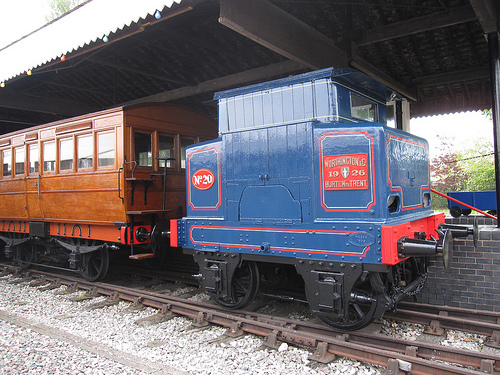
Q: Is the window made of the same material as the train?
A: No, the window is made of glass and the train is made of metal.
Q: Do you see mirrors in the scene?
A: No, there are no mirrors.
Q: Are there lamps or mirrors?
A: No, there are no mirrors or lamps.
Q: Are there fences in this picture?
A: No, there are no fences.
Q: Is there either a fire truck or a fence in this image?
A: No, there are no fences or fire trucks.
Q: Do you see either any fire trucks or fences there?
A: No, there are no fences or fire trucks.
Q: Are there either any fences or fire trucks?
A: No, there are no fences or fire trucks.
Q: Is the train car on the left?
A: Yes, the train car is on the left of the image.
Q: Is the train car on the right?
A: No, the train car is on the left of the image.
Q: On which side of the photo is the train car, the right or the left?
A: The train car is on the left of the image.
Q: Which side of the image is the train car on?
A: The train car is on the left of the image.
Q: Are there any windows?
A: Yes, there is a window.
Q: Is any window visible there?
A: Yes, there is a window.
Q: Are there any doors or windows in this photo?
A: Yes, there is a window.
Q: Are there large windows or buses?
A: Yes, there is a large window.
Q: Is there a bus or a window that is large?
A: Yes, the window is large.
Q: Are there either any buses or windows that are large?
A: Yes, the window is large.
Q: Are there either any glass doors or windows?
A: Yes, there is a glass window.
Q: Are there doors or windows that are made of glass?
A: Yes, the window is made of glass.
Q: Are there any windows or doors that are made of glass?
A: Yes, the window is made of glass.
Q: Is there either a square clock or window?
A: Yes, there is a square window.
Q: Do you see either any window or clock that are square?
A: Yes, the window is square.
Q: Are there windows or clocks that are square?
A: Yes, the window is square.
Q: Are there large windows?
A: Yes, there is a large window.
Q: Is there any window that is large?
A: Yes, there is a window that is large.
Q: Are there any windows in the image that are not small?
A: Yes, there is a large window.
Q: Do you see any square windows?
A: Yes, there is a square window.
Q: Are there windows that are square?
A: Yes, there is a window that is square.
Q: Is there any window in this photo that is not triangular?
A: Yes, there is a square window.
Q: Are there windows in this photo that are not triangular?
A: Yes, there is a square window.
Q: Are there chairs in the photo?
A: No, there are no chairs.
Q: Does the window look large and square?
A: Yes, the window is large and square.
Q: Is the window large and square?
A: Yes, the window is large and square.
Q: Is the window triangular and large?
A: No, the window is large but square.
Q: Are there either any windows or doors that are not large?
A: No, there is a window but it is large.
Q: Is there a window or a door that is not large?
A: No, there is a window but it is large.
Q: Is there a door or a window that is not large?
A: No, there is a window but it is large.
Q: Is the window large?
A: Yes, the window is large.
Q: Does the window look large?
A: Yes, the window is large.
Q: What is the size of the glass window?
A: The window is large.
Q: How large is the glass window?
A: The window is large.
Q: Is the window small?
A: No, the window is large.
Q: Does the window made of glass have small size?
A: No, the window is large.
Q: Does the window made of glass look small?
A: No, the window is large.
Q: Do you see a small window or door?
A: No, there is a window but it is large.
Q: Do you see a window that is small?
A: No, there is a window but it is large.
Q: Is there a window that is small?
A: No, there is a window but it is large.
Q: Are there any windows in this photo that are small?
A: No, there is a window but it is large.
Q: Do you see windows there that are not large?
A: No, there is a window but it is large.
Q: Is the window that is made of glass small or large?
A: The window is large.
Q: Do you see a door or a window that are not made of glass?
A: No, there is a window but it is made of glass.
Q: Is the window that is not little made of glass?
A: Yes, the window is made of glass.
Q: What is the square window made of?
A: The window is made of glass.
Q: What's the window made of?
A: The window is made of glass.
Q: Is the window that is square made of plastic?
A: No, the window is made of glass.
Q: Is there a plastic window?
A: No, there is a window but it is made of glass.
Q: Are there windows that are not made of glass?
A: No, there is a window but it is made of glass.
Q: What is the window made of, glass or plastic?
A: The window is made of glass.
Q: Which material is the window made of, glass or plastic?
A: The window is made of glass.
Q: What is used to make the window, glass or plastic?
A: The window is made of glass.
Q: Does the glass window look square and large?
A: Yes, the window is square and large.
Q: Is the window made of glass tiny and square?
A: No, the window is square but large.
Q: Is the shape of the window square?
A: Yes, the window is square.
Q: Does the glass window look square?
A: Yes, the window is square.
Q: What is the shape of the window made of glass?
A: The window is square.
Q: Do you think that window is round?
A: No, the window is square.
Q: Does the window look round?
A: No, the window is square.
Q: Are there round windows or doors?
A: No, there is a window but it is square.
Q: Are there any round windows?
A: No, there is a window but it is square.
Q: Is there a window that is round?
A: No, there is a window but it is square.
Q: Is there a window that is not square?
A: No, there is a window but it is square.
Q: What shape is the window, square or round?
A: The window is square.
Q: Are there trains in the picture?
A: Yes, there is a train.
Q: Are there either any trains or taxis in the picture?
A: Yes, there is a train.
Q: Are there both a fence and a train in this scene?
A: No, there is a train but no fences.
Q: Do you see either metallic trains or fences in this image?
A: Yes, there is a metal train.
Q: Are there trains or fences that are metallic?
A: Yes, the train is metallic.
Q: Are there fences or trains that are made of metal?
A: Yes, the train is made of metal.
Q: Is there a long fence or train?
A: Yes, there is a long train.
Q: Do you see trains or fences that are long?
A: Yes, the train is long.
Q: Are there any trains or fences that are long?
A: Yes, the train is long.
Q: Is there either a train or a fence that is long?
A: Yes, the train is long.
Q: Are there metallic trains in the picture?
A: Yes, there is a metal train.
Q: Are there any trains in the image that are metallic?
A: Yes, there is a train that is metallic.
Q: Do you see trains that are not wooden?
A: Yes, there is a metallic train.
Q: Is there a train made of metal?
A: Yes, there is a train that is made of metal.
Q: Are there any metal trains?
A: Yes, there is a train that is made of metal.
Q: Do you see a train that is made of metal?
A: Yes, there is a train that is made of metal.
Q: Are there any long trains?
A: Yes, there is a long train.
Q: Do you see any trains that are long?
A: Yes, there is a long train.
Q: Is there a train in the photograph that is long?
A: Yes, there is a train that is long.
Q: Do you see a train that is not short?
A: Yes, there is a long train.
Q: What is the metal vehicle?
A: The vehicle is a train.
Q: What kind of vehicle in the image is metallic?
A: The vehicle is a train.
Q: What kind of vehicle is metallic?
A: The vehicle is a train.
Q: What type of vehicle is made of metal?
A: The vehicle is a train.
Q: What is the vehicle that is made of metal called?
A: The vehicle is a train.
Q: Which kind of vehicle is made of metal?
A: The vehicle is a train.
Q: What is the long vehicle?
A: The vehicle is a train.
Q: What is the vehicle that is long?
A: The vehicle is a train.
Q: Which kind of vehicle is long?
A: The vehicle is a train.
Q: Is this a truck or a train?
A: This is a train.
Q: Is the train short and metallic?
A: No, the train is metallic but long.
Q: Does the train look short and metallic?
A: No, the train is metallic but long.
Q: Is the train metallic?
A: Yes, the train is metallic.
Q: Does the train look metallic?
A: Yes, the train is metallic.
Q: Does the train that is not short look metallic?
A: Yes, the train is metallic.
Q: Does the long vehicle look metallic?
A: Yes, the train is metallic.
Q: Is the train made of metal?
A: Yes, the train is made of metal.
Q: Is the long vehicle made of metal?
A: Yes, the train is made of metal.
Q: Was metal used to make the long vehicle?
A: Yes, the train is made of metal.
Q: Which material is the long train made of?
A: The train is made of metal.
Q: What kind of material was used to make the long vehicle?
A: The train is made of metal.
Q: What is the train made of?
A: The train is made of metal.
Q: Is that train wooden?
A: No, the train is metallic.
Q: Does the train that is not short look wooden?
A: No, the train is metallic.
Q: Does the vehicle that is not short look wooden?
A: No, the train is metallic.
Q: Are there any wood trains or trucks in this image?
A: No, there is a train but it is metallic.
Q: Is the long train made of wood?
A: No, the train is made of metal.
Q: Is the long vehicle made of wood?
A: No, the train is made of metal.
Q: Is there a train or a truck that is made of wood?
A: No, there is a train but it is made of metal.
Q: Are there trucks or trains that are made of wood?
A: No, there is a train but it is made of metal.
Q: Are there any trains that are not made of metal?
A: No, there is a train but it is made of metal.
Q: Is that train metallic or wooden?
A: The train is metallic.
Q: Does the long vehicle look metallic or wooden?
A: The train is metallic.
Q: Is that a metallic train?
A: Yes, that is a metallic train.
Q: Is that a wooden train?
A: No, that is a metallic train.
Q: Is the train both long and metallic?
A: Yes, the train is long and metallic.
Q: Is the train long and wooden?
A: No, the train is long but metallic.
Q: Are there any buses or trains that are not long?
A: No, there is a train but it is long.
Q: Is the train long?
A: Yes, the train is long.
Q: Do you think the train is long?
A: Yes, the train is long.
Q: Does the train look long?
A: Yes, the train is long.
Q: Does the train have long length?
A: Yes, the train is long.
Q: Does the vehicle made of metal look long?
A: Yes, the train is long.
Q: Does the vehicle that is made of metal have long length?
A: Yes, the train is long.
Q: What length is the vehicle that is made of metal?
A: The train is long.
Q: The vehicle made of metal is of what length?
A: The train is long.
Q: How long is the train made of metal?
A: The train is long.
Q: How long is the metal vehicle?
A: The train is long.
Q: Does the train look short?
A: No, the train is long.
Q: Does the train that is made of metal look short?
A: No, the train is long.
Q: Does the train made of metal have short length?
A: No, the train is long.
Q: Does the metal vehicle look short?
A: No, the train is long.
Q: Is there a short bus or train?
A: No, there is a train but it is long.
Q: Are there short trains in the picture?
A: No, there is a train but it is long.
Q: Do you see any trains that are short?
A: No, there is a train but it is long.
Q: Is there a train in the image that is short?
A: No, there is a train but it is long.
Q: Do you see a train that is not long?
A: No, there is a train but it is long.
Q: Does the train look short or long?
A: The train is long.